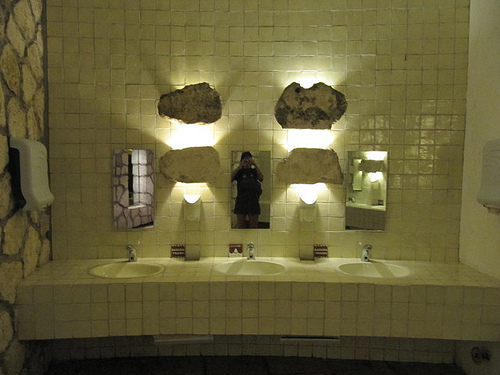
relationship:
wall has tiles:
[2, 1, 500, 356] [14, 3, 474, 360]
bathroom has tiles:
[0, 1, 499, 372] [14, 3, 474, 360]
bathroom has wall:
[0, 1, 499, 372] [2, 1, 500, 356]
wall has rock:
[2, 1, 500, 356] [2, 2, 52, 372]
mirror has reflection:
[225, 144, 277, 235] [233, 153, 266, 228]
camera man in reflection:
[232, 152, 267, 229] [233, 153, 266, 228]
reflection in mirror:
[233, 153, 266, 228] [225, 144, 277, 235]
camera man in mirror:
[232, 152, 267, 229] [225, 144, 277, 235]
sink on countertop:
[332, 240, 414, 282] [15, 256, 500, 298]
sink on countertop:
[209, 240, 294, 285] [15, 256, 500, 298]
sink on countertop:
[87, 239, 168, 284] [15, 256, 500, 298]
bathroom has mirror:
[0, 1, 499, 372] [225, 144, 277, 235]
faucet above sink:
[352, 238, 380, 266] [332, 240, 414, 282]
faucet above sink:
[239, 236, 264, 264] [209, 240, 294, 285]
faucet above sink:
[120, 237, 143, 265] [87, 239, 168, 284]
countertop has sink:
[15, 256, 500, 298] [332, 240, 414, 282]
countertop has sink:
[15, 256, 500, 298] [209, 240, 294, 285]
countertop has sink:
[15, 256, 500, 298] [87, 239, 168, 284]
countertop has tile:
[15, 256, 500, 298] [10, 258, 499, 344]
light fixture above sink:
[177, 190, 208, 229] [209, 240, 294, 285]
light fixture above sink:
[291, 186, 327, 228] [332, 240, 414, 282]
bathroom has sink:
[0, 1, 499, 372] [332, 240, 414, 282]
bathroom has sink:
[0, 1, 499, 372] [209, 240, 294, 285]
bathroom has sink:
[0, 1, 499, 372] [87, 239, 168, 284]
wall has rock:
[0, 0, 55, 374] [2, 2, 52, 372]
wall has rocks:
[0, 0, 55, 374] [2, 1, 56, 374]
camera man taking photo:
[232, 152, 267, 229] [0, 0, 497, 374]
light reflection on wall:
[394, 106, 455, 197] [2, 1, 500, 356]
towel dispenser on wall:
[7, 132, 57, 213] [2, 1, 500, 356]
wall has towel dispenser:
[2, 1, 500, 356] [7, 132, 57, 213]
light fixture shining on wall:
[291, 186, 327, 228] [2, 1, 500, 356]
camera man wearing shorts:
[232, 152, 267, 229] [230, 194, 266, 220]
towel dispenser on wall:
[3, 128, 59, 218] [0, 0, 55, 374]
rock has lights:
[265, 77, 351, 133] [283, 130, 339, 143]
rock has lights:
[150, 78, 228, 127] [167, 124, 219, 138]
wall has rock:
[2, 1, 500, 356] [265, 77, 351, 133]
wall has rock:
[2, 1, 500, 356] [150, 78, 228, 127]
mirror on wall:
[225, 144, 277, 235] [2, 1, 500, 356]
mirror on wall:
[344, 147, 396, 236] [2, 1, 500, 356]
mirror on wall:
[104, 144, 162, 237] [2, 1, 500, 356]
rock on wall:
[265, 77, 351, 133] [2, 1, 500, 356]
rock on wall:
[150, 78, 228, 127] [2, 1, 500, 356]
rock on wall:
[269, 143, 348, 194] [2, 1, 500, 356]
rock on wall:
[155, 142, 229, 188] [2, 1, 500, 356]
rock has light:
[265, 77, 351, 133] [284, 131, 338, 145]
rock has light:
[150, 78, 228, 127] [162, 124, 223, 136]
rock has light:
[269, 143, 348, 194] [289, 188, 334, 194]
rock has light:
[155, 142, 229, 188] [173, 183, 211, 192]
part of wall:
[43, 3, 105, 53] [2, 1, 500, 356]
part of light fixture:
[180, 191, 194, 207] [177, 190, 208, 229]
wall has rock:
[2, 1, 500, 356] [269, 143, 348, 194]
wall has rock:
[2, 1, 500, 356] [155, 142, 229, 188]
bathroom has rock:
[0, 1, 499, 372] [265, 77, 351, 133]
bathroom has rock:
[0, 1, 499, 372] [150, 78, 228, 127]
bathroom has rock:
[0, 1, 499, 372] [269, 143, 348, 194]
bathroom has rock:
[0, 1, 499, 372] [155, 142, 229, 188]